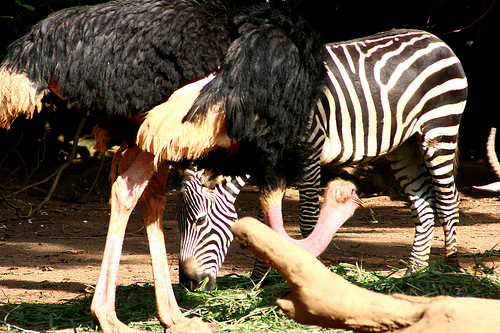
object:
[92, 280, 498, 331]
grass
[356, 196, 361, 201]
nose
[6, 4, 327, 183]
feathers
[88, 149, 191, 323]
legs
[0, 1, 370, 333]
bird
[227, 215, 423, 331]
trunk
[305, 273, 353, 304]
brown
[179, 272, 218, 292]
muzzle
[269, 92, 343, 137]
wall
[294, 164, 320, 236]
leg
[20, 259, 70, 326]
shadow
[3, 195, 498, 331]
ground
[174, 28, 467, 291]
animal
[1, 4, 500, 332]
animal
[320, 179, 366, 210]
head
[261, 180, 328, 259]
neck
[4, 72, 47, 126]
fur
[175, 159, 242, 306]
eating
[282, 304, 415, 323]
log